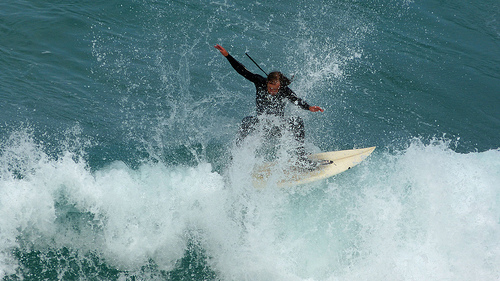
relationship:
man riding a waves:
[213, 39, 332, 173] [0, 9, 500, 281]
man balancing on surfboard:
[216, 39, 325, 187] [233, 141, 374, 197]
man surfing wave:
[213, 39, 332, 173] [63, 141, 170, 229]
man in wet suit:
[213, 39, 332, 173] [206, 48, 317, 148]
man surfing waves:
[213, 39, 332, 173] [102, 149, 189, 223]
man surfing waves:
[213, 39, 332, 173] [124, 151, 194, 231]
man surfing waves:
[213, 39, 332, 173] [92, 136, 201, 257]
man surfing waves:
[213, 39, 332, 173] [116, 160, 203, 250]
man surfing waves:
[213, 39, 332, 173] [70, 149, 201, 272]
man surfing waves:
[213, 39, 332, 173] [90, 176, 239, 263]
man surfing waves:
[213, 39, 332, 173] [143, 141, 225, 241]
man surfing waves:
[213, 39, 332, 173] [63, 122, 239, 258]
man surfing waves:
[213, 39, 332, 173] [84, 158, 182, 266]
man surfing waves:
[213, 39, 332, 173] [104, 184, 205, 260]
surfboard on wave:
[237, 156, 383, 179] [100, 189, 207, 275]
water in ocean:
[46, 130, 160, 240] [67, 141, 186, 241]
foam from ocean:
[4, 130, 494, 279] [7, 9, 492, 279]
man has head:
[213, 39, 332, 173] [263, 72, 290, 96]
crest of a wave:
[0, 129, 498, 264] [3, 119, 498, 276]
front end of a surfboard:
[285, 142, 375, 186] [249, 139, 379, 185]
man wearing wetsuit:
[213, 39, 332, 173] [225, 55, 307, 156]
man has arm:
[213, 39, 332, 173] [209, 42, 268, 90]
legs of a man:
[239, 112, 326, 170] [213, 39, 332, 173]